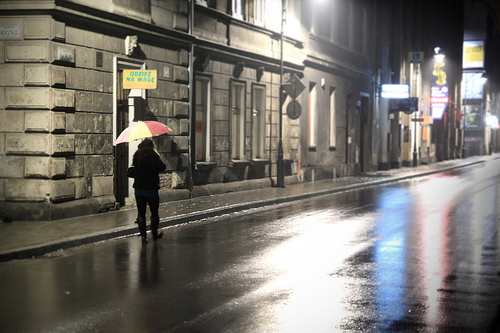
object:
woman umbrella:
[109, 118, 173, 246]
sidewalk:
[2, 155, 500, 251]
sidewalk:
[14, 152, 491, 249]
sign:
[285, 101, 302, 120]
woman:
[131, 140, 166, 241]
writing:
[137, 70, 149, 82]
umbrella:
[110, 121, 173, 145]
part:
[150, 122, 167, 133]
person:
[133, 140, 167, 242]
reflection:
[412, 169, 454, 331]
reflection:
[368, 178, 412, 331]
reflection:
[209, 206, 381, 332]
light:
[379, 83, 411, 99]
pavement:
[0, 151, 500, 332]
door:
[357, 92, 371, 174]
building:
[0, 1, 374, 215]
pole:
[277, 12, 285, 188]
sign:
[120, 67, 158, 90]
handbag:
[126, 167, 138, 178]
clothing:
[132, 149, 166, 216]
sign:
[381, 83, 410, 99]